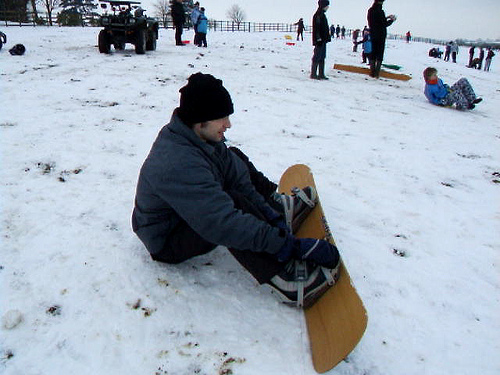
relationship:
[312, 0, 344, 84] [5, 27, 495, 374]
person sitting on slope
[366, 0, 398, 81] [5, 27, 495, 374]
adult sitting on slope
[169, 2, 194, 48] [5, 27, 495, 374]
person sitting on slope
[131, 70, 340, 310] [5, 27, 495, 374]
man sitting on slope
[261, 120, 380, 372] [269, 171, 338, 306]
snowboard strapped to feet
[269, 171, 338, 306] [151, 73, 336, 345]
feet of man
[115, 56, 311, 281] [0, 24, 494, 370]
man sitting on snow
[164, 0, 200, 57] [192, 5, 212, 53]
adult with children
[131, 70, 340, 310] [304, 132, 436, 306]
man on snow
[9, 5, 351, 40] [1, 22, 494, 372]
fencing on top of hill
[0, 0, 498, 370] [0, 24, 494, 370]
ground covered by snow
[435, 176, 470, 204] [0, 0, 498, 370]
dark holes are in ground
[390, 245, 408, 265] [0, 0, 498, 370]
dark holes are in ground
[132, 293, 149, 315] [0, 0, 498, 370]
dark holes are in ground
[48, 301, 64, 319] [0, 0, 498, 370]
dark holes are in ground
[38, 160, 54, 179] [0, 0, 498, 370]
dark holes are in ground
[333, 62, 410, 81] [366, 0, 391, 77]
object between adult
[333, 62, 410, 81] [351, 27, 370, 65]
object between child